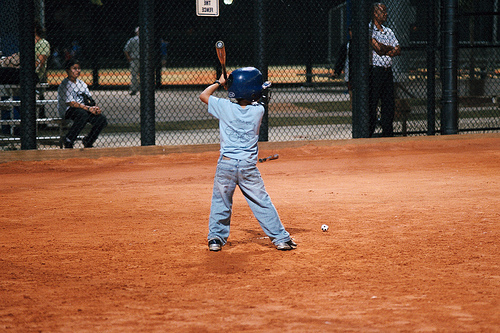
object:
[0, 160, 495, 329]
ground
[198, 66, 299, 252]
boy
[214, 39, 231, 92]
bat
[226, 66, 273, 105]
helmet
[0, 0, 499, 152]
fence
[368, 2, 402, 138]
man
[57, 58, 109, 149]
kid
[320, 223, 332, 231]
ball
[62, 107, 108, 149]
jeans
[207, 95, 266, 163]
shirt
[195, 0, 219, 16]
sign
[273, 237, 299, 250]
shoes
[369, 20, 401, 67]
shirt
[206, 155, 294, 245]
pants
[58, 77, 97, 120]
shirt